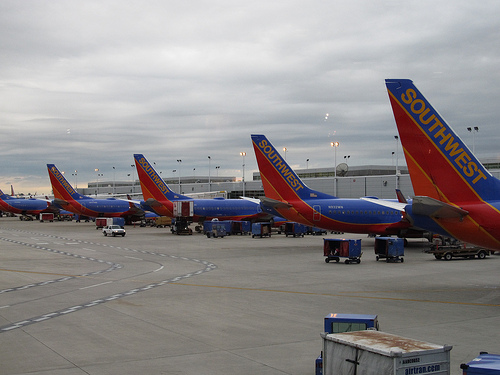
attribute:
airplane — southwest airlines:
[381, 75, 498, 255]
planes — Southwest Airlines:
[0, 75, 498, 257]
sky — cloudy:
[34, 11, 489, 208]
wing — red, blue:
[373, 67, 497, 206]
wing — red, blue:
[245, 125, 309, 207]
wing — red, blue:
[128, 142, 182, 214]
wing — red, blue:
[40, 154, 90, 211]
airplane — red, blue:
[43, 154, 159, 226]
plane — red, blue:
[109, 154, 255, 234]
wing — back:
[247, 128, 327, 218]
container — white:
[323, 326, 452, 373]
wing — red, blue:
[3, 197, 49, 209]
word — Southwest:
[258, 137, 305, 193]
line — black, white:
[13, 317, 32, 326]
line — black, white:
[84, 296, 103, 311]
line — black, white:
[76, 280, 115, 293]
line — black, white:
[149, 258, 169, 275]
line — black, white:
[52, 275, 76, 287]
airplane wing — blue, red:
[379, 73, 495, 198]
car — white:
[88, 217, 140, 248]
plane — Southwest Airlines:
[384, 77, 493, 263]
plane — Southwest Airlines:
[249, 130, 407, 237]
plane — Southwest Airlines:
[133, 151, 252, 236]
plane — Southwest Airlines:
[47, 161, 140, 226]